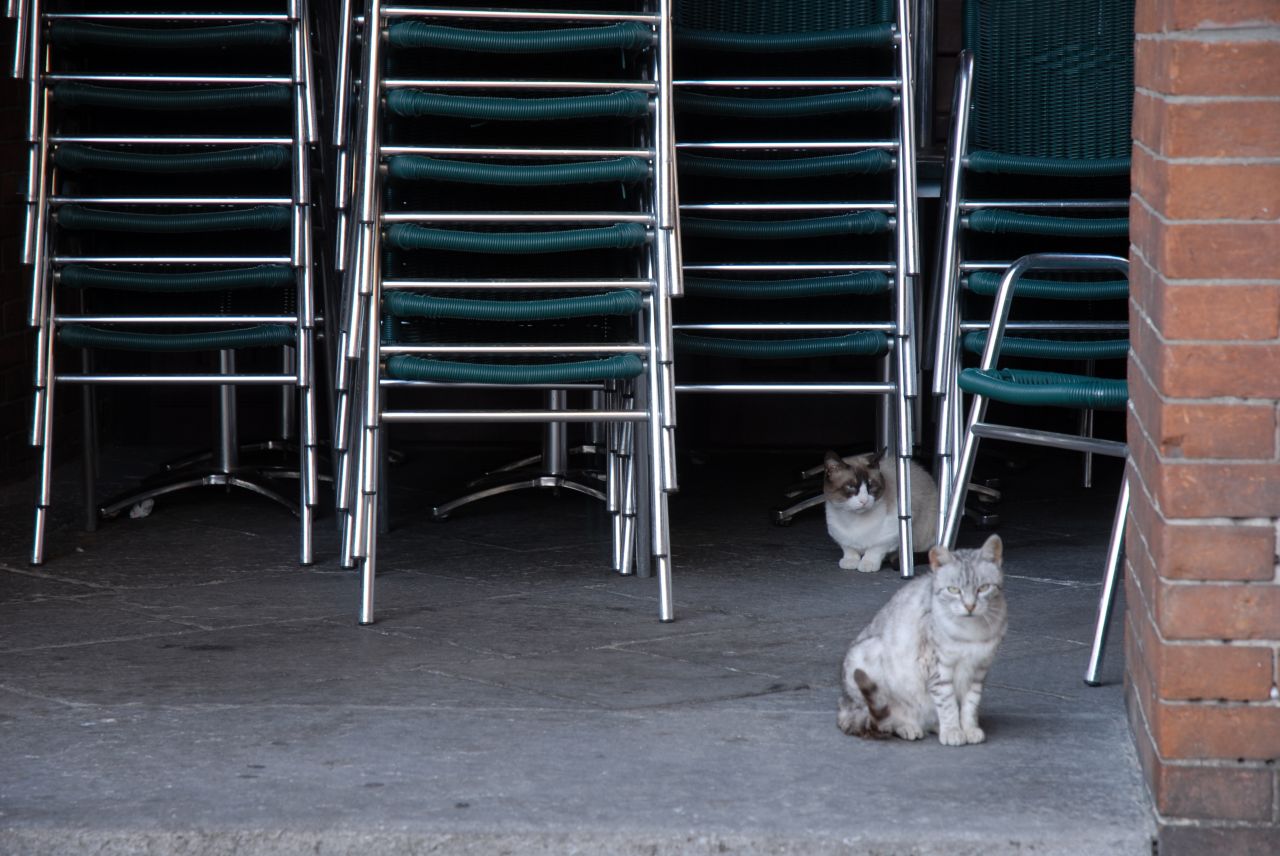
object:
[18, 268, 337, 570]
chairs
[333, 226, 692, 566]
chairs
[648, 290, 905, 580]
chairs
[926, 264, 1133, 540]
chairs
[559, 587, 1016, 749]
concrete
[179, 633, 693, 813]
concrete floor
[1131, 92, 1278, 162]
brick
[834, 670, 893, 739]
tail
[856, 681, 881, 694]
rings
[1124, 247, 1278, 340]
brick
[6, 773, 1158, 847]
edge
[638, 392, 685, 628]
chrome legs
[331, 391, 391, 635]
chrome legs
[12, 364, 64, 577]
chrome legs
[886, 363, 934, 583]
chrome legs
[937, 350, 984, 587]
chrome legs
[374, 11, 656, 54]
seats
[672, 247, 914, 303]
seats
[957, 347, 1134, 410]
seats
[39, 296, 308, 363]
seats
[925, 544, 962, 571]
ears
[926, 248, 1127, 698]
chair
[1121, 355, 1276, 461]
brick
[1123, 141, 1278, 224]
brick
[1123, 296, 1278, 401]
brick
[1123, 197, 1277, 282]
brick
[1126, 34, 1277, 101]
brick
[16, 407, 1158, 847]
floor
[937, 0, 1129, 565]
chair stack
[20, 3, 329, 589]
chair stack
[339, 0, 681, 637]
chair stack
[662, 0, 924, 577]
chair stack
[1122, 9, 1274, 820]
brick wall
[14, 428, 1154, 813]
sidewalk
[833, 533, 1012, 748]
cat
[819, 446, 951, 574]
cat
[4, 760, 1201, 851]
step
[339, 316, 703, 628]
chair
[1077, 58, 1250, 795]
brick corner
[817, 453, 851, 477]
ears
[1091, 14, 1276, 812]
wall